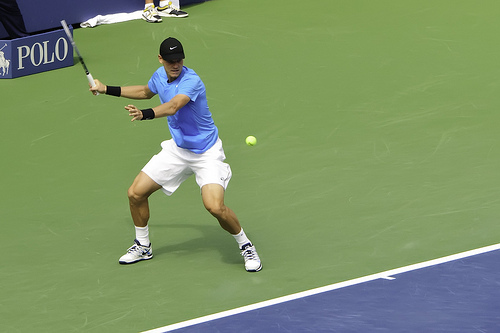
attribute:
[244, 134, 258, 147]
tennis ball — being hit, green, bright, yellow, green color, color green, mid air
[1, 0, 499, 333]
tennis court — green, blue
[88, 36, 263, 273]
man — playing tennis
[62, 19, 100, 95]
racket — white, black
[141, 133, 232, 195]
shorts — white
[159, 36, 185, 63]
cap — black, nike brand, nike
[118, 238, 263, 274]
shoes — black yellow, white, black, white black, yellow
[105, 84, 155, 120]
wristbands — black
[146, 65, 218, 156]
shirt — sporty, blue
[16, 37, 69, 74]
polo advertisement — white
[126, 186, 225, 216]
knees — bent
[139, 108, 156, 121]
wrist band — black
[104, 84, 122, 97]
wrist band — black